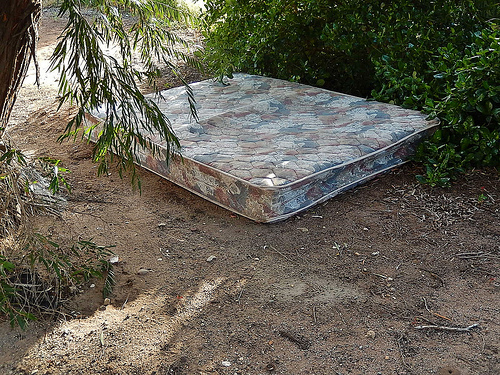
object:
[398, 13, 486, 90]
plants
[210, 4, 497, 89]
tree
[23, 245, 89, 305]
branches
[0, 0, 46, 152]
tree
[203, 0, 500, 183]
leaves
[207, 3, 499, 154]
plants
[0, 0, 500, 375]
dirt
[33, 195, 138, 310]
roots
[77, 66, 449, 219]
matress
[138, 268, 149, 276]
rock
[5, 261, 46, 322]
hole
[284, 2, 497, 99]
tree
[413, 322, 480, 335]
stick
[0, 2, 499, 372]
pathway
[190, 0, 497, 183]
bush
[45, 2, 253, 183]
leafy/tree branch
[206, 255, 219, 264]
rocks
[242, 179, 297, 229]
mattress corner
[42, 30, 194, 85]
sunlight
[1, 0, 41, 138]
trunk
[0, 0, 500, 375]
ground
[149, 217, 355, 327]
ground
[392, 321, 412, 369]
stick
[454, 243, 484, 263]
stick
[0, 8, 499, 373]
sand